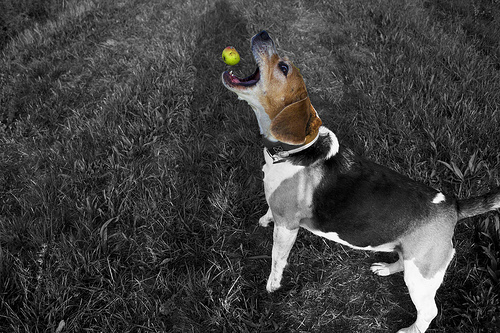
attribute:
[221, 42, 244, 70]
fruit — small, green, round, yellow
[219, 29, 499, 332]
dog — beagle, four legged, white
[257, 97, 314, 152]
ear — brown, floppy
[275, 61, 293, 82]
eye — black, small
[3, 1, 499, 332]
grass — white, high level, tall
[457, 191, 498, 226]
tail — short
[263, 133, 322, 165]
collar — white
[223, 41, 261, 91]
mouth — open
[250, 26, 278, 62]
nose — black, small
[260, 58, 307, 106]
face — brown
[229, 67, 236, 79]
tooth — white, sharp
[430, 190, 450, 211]
spot — white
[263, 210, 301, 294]
front leg — white